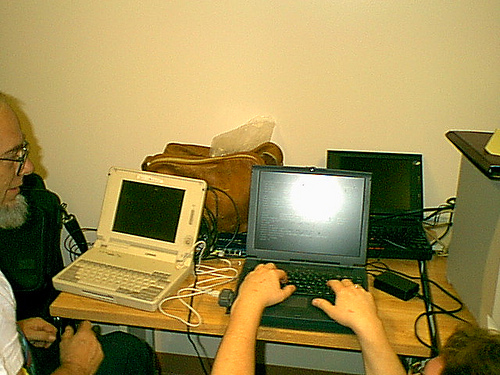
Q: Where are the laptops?
A: On the table.